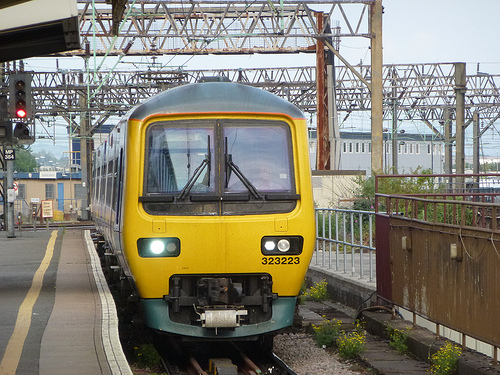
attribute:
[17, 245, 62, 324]
line — at edge of platform, double, painted, yellow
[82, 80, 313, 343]
train — yellow, riding down track, at train station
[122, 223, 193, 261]
light — on, on front of train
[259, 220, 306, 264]
light — off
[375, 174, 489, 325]
fence — metal, brown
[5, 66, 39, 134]
traffic signal — showing red, black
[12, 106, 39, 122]
light — red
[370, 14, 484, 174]
poles — wooden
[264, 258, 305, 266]
323223 — on front of train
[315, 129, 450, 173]
building — gray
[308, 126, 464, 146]
roof — black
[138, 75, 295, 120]
green top — on train